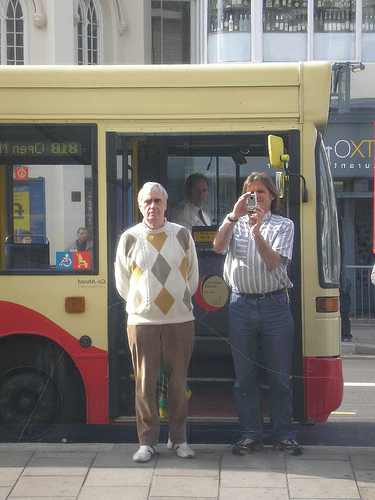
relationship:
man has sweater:
[115, 181, 200, 462] [109, 219, 207, 320]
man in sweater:
[115, 181, 199, 460] [114, 218, 199, 323]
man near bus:
[115, 181, 199, 460] [0, 59, 344, 439]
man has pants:
[115, 181, 199, 460] [125, 318, 194, 443]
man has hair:
[217, 177, 305, 457] [239, 167, 282, 199]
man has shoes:
[217, 177, 305, 457] [235, 433, 305, 461]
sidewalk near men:
[1, 442, 373, 498] [114, 181, 199, 463]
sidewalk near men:
[1, 442, 373, 498] [211, 170, 304, 456]